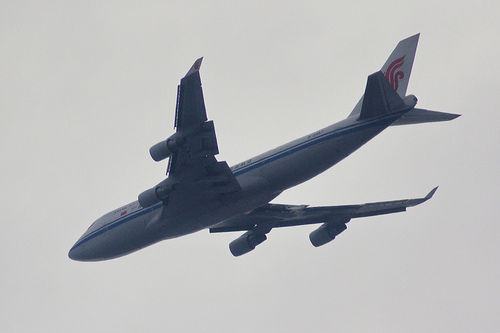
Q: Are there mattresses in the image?
A: No, there are no mattresses.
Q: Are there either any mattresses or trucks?
A: No, there are no mattresses or trucks.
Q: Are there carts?
A: No, there are no carts.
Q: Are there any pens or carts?
A: No, there are no carts or pens.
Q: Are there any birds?
A: No, there are no birds.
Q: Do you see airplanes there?
A: Yes, there is an airplane.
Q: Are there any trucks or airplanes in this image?
A: Yes, there is an airplane.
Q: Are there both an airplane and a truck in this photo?
A: No, there is an airplane but no trucks.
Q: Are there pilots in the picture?
A: No, there are no pilots.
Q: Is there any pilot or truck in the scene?
A: No, there are no pilots or trucks.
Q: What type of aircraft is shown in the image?
A: The aircraft is an airplane.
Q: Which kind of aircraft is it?
A: The aircraft is an airplane.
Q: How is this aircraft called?
A: That is an airplane.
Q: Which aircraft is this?
A: That is an airplane.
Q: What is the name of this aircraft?
A: That is an airplane.